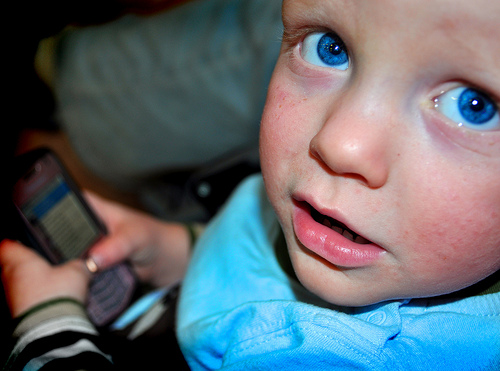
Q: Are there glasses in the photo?
A: No, there are no glasses.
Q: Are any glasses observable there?
A: No, there are no glasses.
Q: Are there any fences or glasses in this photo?
A: No, there are no glasses or fences.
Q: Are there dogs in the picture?
A: No, there are no dogs.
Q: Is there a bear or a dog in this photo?
A: No, there are no dogs or bears.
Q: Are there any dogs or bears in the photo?
A: No, there are no dogs or bears.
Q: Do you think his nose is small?
A: Yes, the nose is small.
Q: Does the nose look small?
A: Yes, the nose is small.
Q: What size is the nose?
A: The nose is small.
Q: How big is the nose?
A: The nose is small.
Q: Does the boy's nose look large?
A: No, the nose is small.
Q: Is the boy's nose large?
A: No, the nose is small.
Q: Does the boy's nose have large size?
A: No, the nose is small.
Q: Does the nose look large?
A: No, the nose is small.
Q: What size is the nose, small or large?
A: The nose is small.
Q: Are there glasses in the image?
A: No, there are no glasses.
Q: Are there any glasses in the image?
A: No, there are no glasses.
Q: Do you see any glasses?
A: No, there are no glasses.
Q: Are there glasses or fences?
A: No, there are no glasses or fences.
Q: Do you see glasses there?
A: No, there are no glasses.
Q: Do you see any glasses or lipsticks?
A: No, there are no glasses or lipsticks.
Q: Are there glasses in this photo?
A: No, there are no glasses.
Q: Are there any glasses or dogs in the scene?
A: No, there are no glasses or dogs.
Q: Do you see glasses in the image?
A: No, there are no glasses.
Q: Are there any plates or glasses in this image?
A: No, there are no glasses or plates.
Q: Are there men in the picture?
A: No, there are no men.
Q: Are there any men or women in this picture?
A: No, there are no men or women.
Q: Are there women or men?
A: No, there are no men or women.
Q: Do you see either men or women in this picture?
A: No, there are no men or women.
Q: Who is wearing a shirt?
A: The boy is wearing a shirt.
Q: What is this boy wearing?
A: The boy is wearing a shirt.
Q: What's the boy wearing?
A: The boy is wearing a shirt.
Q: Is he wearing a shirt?
A: Yes, the boy is wearing a shirt.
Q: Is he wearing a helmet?
A: No, the boy is wearing a shirt.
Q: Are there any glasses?
A: No, there are no glasses.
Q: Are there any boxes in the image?
A: No, there are no boxes.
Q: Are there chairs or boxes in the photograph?
A: No, there are no boxes or chairs.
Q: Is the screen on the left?
A: Yes, the screen is on the left of the image.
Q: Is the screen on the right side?
A: No, the screen is on the left of the image.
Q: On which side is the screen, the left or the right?
A: The screen is on the left of the image.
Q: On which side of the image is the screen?
A: The screen is on the left of the image.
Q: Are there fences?
A: No, there are no fences.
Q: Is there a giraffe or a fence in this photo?
A: No, there are no fences or giraffes.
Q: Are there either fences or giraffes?
A: No, there are no fences or giraffes.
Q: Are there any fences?
A: No, there are no fences.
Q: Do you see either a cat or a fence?
A: No, there are no fences or cats.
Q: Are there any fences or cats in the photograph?
A: No, there are no fences or cats.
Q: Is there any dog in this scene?
A: No, there are no dogs.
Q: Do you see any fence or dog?
A: No, there are no dogs or fences.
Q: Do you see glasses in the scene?
A: No, there are no glasses.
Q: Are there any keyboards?
A: Yes, there is a keyboard.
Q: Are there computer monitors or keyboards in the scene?
A: Yes, there is a keyboard.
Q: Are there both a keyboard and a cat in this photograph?
A: No, there is a keyboard but no cats.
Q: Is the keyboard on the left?
A: Yes, the keyboard is on the left of the image.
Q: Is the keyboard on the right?
A: No, the keyboard is on the left of the image.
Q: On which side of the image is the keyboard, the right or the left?
A: The keyboard is on the left of the image.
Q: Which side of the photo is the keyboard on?
A: The keyboard is on the left of the image.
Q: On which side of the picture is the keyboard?
A: The keyboard is on the left of the image.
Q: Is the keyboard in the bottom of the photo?
A: Yes, the keyboard is in the bottom of the image.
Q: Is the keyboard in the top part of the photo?
A: No, the keyboard is in the bottom of the image.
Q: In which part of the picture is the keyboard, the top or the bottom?
A: The keyboard is in the bottom of the image.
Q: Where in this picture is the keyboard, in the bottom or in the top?
A: The keyboard is in the bottom of the image.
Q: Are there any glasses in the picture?
A: No, there are no glasses.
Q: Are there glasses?
A: No, there are no glasses.